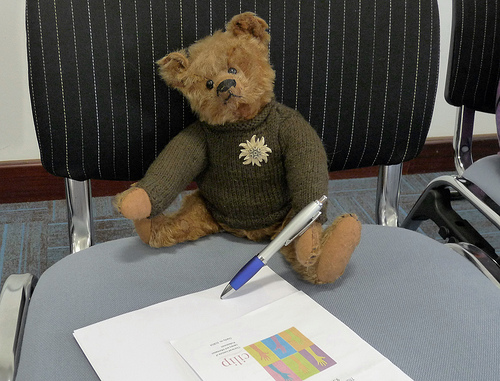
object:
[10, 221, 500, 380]
cushion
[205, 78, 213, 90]
eye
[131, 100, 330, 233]
sweater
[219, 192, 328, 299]
pen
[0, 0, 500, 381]
chair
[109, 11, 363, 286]
bear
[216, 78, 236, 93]
nose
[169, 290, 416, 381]
papers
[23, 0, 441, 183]
back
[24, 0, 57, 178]
stripes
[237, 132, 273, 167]
design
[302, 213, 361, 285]
foot